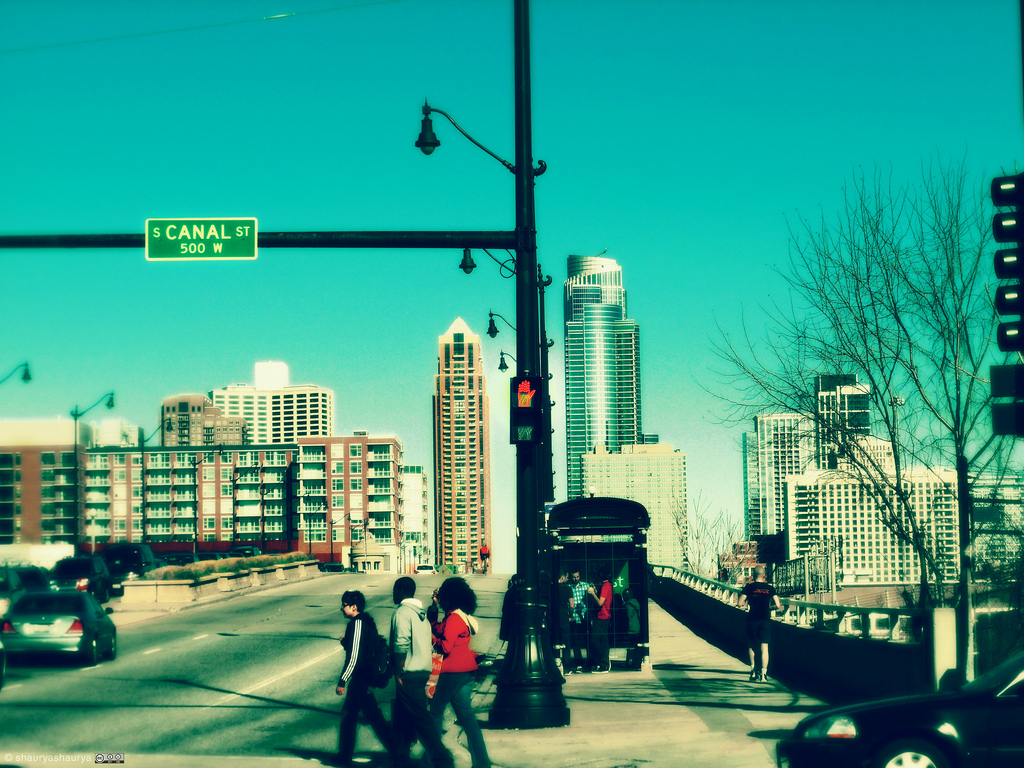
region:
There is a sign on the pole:
[109, 214, 531, 275]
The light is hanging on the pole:
[412, 88, 543, 243]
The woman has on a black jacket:
[321, 593, 391, 759]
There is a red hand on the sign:
[504, 371, 540, 447]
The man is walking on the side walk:
[723, 559, 782, 687]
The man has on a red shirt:
[584, 574, 627, 676]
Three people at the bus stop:
[546, 505, 648, 676]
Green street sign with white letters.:
[134, 215, 259, 264]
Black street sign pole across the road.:
[8, 203, 531, 249]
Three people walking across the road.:
[333, 549, 520, 765]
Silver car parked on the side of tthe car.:
[11, 557, 128, 665]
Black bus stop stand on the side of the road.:
[550, 484, 646, 665]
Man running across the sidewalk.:
[725, 560, 786, 685]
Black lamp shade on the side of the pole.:
[400, 78, 461, 186]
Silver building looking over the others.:
[555, 247, 587, 516]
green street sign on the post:
[144, 212, 266, 267]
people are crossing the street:
[322, 574, 500, 761]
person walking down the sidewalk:
[732, 550, 784, 674]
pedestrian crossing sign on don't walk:
[502, 356, 548, 455]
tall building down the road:
[426, 320, 497, 577]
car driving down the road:
[12, 575, 129, 659]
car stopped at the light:
[766, 632, 1019, 766]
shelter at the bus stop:
[545, 496, 660, 684]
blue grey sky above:
[613, 34, 869, 156]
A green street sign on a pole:
[144, 209, 261, 261]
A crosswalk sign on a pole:
[505, 361, 547, 454]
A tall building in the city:
[432, 311, 491, 577]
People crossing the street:
[330, 578, 487, 765]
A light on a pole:
[414, 99, 444, 158]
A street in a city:
[0, 572, 526, 760]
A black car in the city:
[757, 648, 1021, 765]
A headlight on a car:
[801, 702, 859, 741]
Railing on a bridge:
[653, 556, 929, 658]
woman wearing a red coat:
[426, 609, 472, 674]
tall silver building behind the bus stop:
[562, 240, 654, 438]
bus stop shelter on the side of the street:
[551, 486, 662, 684]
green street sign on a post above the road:
[139, 212, 261, 267]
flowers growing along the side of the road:
[139, 537, 321, 592]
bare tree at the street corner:
[795, 186, 1010, 684]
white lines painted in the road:
[138, 619, 222, 665]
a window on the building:
[440, 462, 469, 492]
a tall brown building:
[419, 319, 500, 582]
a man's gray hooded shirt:
[386, 588, 435, 674]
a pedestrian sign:
[506, 377, 544, 419]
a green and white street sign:
[146, 215, 261, 264]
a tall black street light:
[409, 97, 561, 551]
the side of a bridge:
[646, 541, 947, 703]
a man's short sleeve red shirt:
[593, 582, 614, 617]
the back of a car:
[1, 576, 126, 671]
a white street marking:
[190, 617, 216, 650]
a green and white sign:
[145, 217, 259, 259]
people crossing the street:
[0, 572, 496, 766]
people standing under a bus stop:
[547, 496, 650, 670]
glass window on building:
[148, 454, 162, 471]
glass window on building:
[174, 448, 195, 465]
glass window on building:
[147, 467, 167, 483]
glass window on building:
[167, 465, 197, 485]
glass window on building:
[144, 486, 170, 505]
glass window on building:
[173, 484, 194, 501]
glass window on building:
[145, 500, 164, 517]